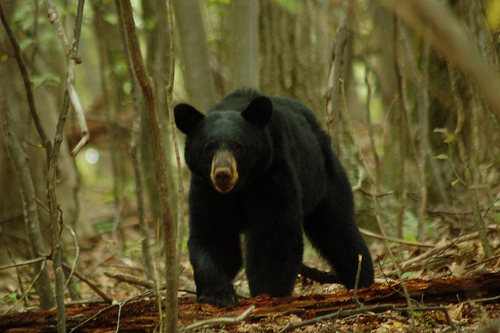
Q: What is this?
A: Bear.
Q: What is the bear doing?
A: Walking.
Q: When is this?
A: Daytime.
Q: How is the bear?
A: Walking.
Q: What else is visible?
A: Trees.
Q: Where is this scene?
A: In the wilderness.